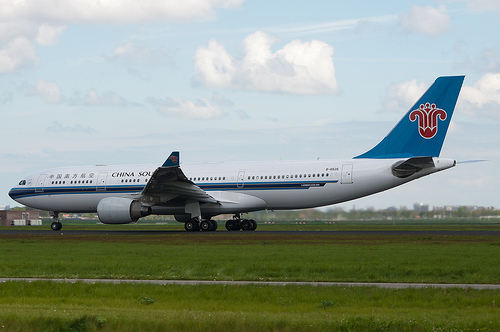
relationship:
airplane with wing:
[10, 72, 492, 241] [139, 153, 215, 222]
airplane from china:
[10, 72, 492, 241] [108, 169, 138, 179]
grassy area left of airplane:
[5, 237, 499, 284] [10, 72, 492, 241]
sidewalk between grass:
[0, 273, 496, 299] [0, 237, 499, 330]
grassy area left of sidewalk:
[5, 237, 499, 284] [0, 273, 496, 299]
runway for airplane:
[4, 227, 499, 244] [10, 75, 487, 230]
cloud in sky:
[193, 29, 344, 97] [0, 0, 496, 181]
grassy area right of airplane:
[4, 222, 498, 231] [10, 75, 487, 230]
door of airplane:
[97, 172, 110, 185] [10, 72, 492, 241]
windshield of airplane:
[18, 179, 30, 187] [10, 72, 492, 241]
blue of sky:
[63, 24, 107, 70] [0, 0, 496, 181]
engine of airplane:
[92, 197, 155, 227] [10, 75, 487, 230]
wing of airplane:
[139, 153, 215, 222] [10, 75, 487, 230]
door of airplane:
[97, 172, 110, 185] [10, 75, 487, 230]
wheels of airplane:
[49, 220, 259, 232] [10, 75, 487, 230]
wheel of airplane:
[48, 221, 63, 228] [10, 75, 487, 230]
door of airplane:
[338, 162, 356, 186] [10, 75, 487, 230]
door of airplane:
[234, 169, 250, 189] [10, 75, 487, 230]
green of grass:
[4, 282, 500, 329] [0, 237, 499, 330]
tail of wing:
[352, 71, 471, 157] [139, 153, 215, 222]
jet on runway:
[10, 72, 492, 241] [4, 227, 499, 244]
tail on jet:
[352, 71, 471, 157] [10, 72, 492, 241]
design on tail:
[409, 102, 447, 138] [352, 71, 471, 157]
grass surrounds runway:
[0, 237, 499, 330] [4, 227, 499, 244]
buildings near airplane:
[0, 206, 46, 227] [10, 75, 487, 230]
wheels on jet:
[49, 220, 259, 232] [10, 72, 492, 241]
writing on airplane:
[108, 169, 154, 180] [10, 75, 487, 230]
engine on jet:
[92, 197, 155, 227] [10, 72, 492, 241]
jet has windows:
[10, 72, 492, 241] [46, 172, 337, 182]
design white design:
[409, 102, 447, 138] [409, 102, 447, 138]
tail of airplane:
[352, 71, 471, 157] [10, 72, 492, 241]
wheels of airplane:
[49, 220, 259, 232] [10, 72, 492, 241]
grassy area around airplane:
[5, 237, 499, 284] [10, 72, 492, 241]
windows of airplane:
[46, 172, 337, 182] [10, 75, 487, 230]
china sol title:
[108, 169, 138, 179] [113, 169, 153, 177]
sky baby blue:
[0, 0, 496, 181] [63, 24, 107, 70]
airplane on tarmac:
[10, 72, 492, 241] [5, 218, 499, 241]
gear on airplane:
[43, 211, 267, 237] [10, 75, 487, 230]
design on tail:
[400, 104, 449, 136] [352, 71, 471, 157]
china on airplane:
[108, 169, 138, 179] [10, 75, 487, 230]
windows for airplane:
[46, 172, 337, 182] [10, 75, 487, 230]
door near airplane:
[97, 172, 110, 185] [10, 75, 487, 230]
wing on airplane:
[139, 153, 215, 222] [10, 75, 487, 230]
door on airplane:
[338, 162, 356, 186] [10, 75, 487, 230]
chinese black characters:
[49, 169, 97, 180] [46, 170, 98, 180]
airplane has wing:
[10, 72, 492, 241] [139, 153, 215, 222]